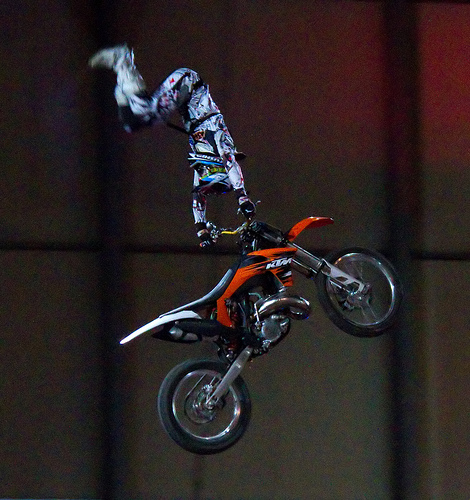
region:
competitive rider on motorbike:
[83, 36, 414, 458]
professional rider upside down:
[83, 38, 273, 264]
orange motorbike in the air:
[124, 198, 406, 459]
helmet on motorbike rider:
[183, 146, 245, 201]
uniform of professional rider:
[124, 67, 236, 163]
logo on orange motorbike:
[251, 247, 302, 284]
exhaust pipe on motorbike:
[185, 292, 278, 351]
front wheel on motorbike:
[313, 234, 407, 340]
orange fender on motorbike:
[285, 209, 339, 245]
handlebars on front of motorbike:
[198, 201, 270, 250]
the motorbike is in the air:
[189, 231, 397, 446]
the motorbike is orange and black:
[130, 239, 422, 424]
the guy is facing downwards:
[86, 50, 262, 218]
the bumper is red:
[288, 209, 341, 239]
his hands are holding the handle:
[166, 200, 296, 253]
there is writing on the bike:
[254, 252, 305, 279]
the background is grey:
[298, 354, 412, 462]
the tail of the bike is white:
[120, 309, 173, 341]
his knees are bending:
[89, 74, 185, 132]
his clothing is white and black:
[161, 72, 247, 156]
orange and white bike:
[113, 200, 405, 458]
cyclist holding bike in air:
[84, 36, 407, 473]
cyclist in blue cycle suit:
[84, 37, 267, 255]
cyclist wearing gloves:
[87, 40, 269, 250]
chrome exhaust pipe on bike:
[255, 286, 312, 343]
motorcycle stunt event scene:
[6, 9, 469, 487]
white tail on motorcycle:
[114, 304, 196, 355]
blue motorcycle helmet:
[184, 144, 235, 206]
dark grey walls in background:
[7, 12, 468, 488]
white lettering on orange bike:
[262, 252, 298, 273]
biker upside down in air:
[89, 34, 405, 455]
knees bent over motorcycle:
[88, 43, 247, 152]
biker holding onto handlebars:
[185, 206, 277, 252]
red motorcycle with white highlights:
[111, 203, 411, 452]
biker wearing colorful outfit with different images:
[86, 34, 268, 241]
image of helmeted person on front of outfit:
[184, 120, 216, 158]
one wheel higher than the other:
[105, 237, 400, 454]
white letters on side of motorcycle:
[244, 248, 302, 284]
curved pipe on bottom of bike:
[239, 286, 316, 325]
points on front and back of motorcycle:
[108, 199, 362, 370]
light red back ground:
[276, 43, 459, 121]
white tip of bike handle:
[114, 312, 151, 344]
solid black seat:
[141, 271, 259, 309]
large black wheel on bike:
[127, 343, 272, 448]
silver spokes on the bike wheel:
[207, 355, 272, 401]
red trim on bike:
[208, 256, 299, 344]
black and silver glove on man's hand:
[193, 212, 283, 260]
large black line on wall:
[48, 221, 176, 266]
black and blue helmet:
[188, 156, 244, 190]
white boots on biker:
[100, 37, 149, 105]